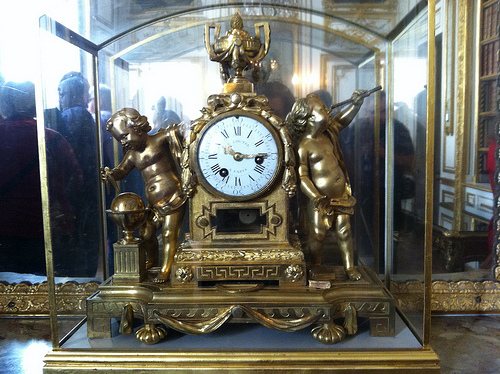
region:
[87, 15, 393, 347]
the clock is close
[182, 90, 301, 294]
the clock is golden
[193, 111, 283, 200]
the clock reads 10:14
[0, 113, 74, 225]
the shirt is red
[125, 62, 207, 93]
the light is bright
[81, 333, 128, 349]
the bottom is blue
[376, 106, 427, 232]
the case is glass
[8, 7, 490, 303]
the mirror is behind the clock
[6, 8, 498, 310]
the mirror is big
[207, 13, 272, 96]
the trophy is on top of the clock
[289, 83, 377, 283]
Statue on right side of clock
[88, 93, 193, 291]
Statue on left side of clock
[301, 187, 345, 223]
Statue hand on crouch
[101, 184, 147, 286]
Statue with ball on top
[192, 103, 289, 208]
white Clock on statue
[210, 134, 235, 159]
Short hand on clock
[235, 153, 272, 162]
Long hand on clock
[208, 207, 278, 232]
Clock bell inside clock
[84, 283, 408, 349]
Bottom of clock stand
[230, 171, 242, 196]
Numeral six on clock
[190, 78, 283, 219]
clock face is white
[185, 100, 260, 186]
clock numbers are roman numerals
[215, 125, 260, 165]
clock hands are bronze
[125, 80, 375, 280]
children are sculptures of clock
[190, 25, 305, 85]
carving on top of clock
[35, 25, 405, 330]
clock inside glass case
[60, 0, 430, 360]
glass case on wood table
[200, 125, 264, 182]
roman numerals are black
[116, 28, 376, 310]
clock is made of bronze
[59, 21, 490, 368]
clock is in museum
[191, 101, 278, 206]
clock uses roman numerals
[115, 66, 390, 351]
clock is bronze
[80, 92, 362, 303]
children are statues on clock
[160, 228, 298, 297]
decorative design on clock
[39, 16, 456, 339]
clock in glass case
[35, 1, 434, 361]
glass case on brown table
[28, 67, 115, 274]
people looking at clock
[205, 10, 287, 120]
statue on top of clock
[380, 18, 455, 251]
case has bronze frame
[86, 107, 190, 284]
golden cherub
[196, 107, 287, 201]
round white and black clock face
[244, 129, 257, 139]
roman numeral one on the clock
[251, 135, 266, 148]
roman number two on a clock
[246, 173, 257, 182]
roman numeral four on a clock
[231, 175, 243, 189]
roman numeral five on a clock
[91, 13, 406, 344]
golden clock with a golden cherubs design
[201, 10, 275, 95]
golden top of a clock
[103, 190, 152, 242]
golden globe design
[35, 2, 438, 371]
golden clock behind a glass